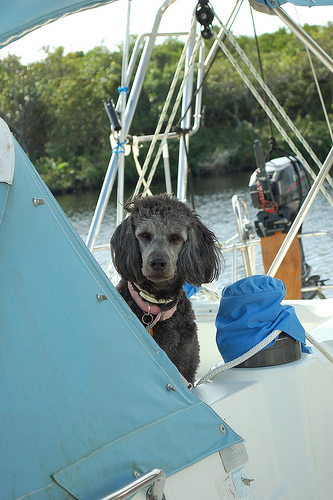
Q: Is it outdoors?
A: Yes, it is outdoors.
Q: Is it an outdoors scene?
A: Yes, it is outdoors.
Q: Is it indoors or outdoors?
A: It is outdoors.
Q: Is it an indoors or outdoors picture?
A: It is outdoors.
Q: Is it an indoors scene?
A: No, it is outdoors.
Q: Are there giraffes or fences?
A: No, there are no fences or giraffes.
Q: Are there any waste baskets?
A: No, there are no waste baskets.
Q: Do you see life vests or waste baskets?
A: No, there are no waste baskets or life vests.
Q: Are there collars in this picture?
A: Yes, there is a collar.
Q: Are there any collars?
A: Yes, there is a collar.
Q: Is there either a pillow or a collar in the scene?
A: Yes, there is a collar.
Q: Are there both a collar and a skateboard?
A: No, there is a collar but no skateboards.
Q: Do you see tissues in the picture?
A: No, there are no tissues.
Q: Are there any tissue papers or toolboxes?
A: No, there are no tissue papers or toolboxes.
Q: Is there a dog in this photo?
A: Yes, there is a dog.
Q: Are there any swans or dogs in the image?
A: Yes, there is a dog.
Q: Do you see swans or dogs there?
A: Yes, there is a dog.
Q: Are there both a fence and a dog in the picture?
A: No, there is a dog but no fences.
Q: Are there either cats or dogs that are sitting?
A: Yes, the dog is sitting.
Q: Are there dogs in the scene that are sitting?
A: Yes, there is a dog that is sitting.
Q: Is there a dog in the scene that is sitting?
A: Yes, there is a dog that is sitting.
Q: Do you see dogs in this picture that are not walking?
A: Yes, there is a dog that is sitting .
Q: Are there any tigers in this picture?
A: No, there are no tigers.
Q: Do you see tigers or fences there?
A: No, there are no tigers or fences.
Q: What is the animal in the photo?
A: The animal is a dog.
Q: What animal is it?
A: The animal is a dog.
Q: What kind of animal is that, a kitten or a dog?
A: This is a dog.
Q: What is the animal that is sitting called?
A: The animal is a dog.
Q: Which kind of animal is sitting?
A: The animal is a dog.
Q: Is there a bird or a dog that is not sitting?
A: No, there is a dog but it is sitting.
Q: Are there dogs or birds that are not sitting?
A: No, there is a dog but it is sitting.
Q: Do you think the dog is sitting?
A: Yes, the dog is sitting.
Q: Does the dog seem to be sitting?
A: Yes, the dog is sitting.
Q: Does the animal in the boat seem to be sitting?
A: Yes, the dog is sitting.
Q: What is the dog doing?
A: The dog is sitting.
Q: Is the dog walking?
A: No, the dog is sitting.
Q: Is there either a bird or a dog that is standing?
A: No, there is a dog but it is sitting.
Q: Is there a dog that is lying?
A: No, there is a dog but it is sitting.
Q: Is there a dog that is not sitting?
A: No, there is a dog but it is sitting.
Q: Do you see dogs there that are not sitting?
A: No, there is a dog but it is sitting.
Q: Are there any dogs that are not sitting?
A: No, there is a dog but it is sitting.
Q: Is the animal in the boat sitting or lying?
A: The dog is sitting.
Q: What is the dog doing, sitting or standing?
A: The dog is sitting.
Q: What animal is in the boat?
A: The dog is in the boat.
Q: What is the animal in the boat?
A: The animal is a dog.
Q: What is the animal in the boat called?
A: The animal is a dog.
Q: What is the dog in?
A: The dog is in the boat.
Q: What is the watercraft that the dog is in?
A: The watercraft is a boat.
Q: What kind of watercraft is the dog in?
A: The dog is in the boat.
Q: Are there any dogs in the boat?
A: Yes, there is a dog in the boat.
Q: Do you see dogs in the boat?
A: Yes, there is a dog in the boat.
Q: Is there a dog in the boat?
A: Yes, there is a dog in the boat.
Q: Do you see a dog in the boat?
A: Yes, there is a dog in the boat.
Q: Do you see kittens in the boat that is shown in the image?
A: No, there is a dog in the boat.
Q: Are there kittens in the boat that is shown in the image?
A: No, there is a dog in the boat.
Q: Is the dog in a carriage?
A: No, the dog is in the boat.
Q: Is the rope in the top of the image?
A: Yes, the rope is in the top of the image.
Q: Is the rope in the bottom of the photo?
A: No, the rope is in the top of the image.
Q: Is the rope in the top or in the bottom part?
A: The rope is in the top of the image.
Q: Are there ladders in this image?
A: No, there are no ladders.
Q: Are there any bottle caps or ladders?
A: No, there are no ladders or bottle caps.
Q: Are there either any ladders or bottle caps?
A: No, there are no ladders or bottle caps.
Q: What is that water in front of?
A: The water is in front of the trees.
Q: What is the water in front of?
A: The water is in front of the trees.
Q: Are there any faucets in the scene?
A: No, there are no faucets.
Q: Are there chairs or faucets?
A: No, there are no faucets or chairs.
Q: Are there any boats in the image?
A: Yes, there is a boat.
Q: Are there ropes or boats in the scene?
A: Yes, there is a boat.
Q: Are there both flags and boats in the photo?
A: No, there is a boat but no flags.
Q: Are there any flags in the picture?
A: No, there are no flags.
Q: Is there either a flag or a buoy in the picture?
A: No, there are no flags or buoys.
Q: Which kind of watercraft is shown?
A: The watercraft is a boat.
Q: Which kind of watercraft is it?
A: The watercraft is a boat.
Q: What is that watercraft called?
A: That is a boat.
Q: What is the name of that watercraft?
A: That is a boat.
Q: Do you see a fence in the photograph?
A: No, there are no fences.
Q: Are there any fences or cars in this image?
A: No, there are no fences or cars.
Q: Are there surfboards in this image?
A: No, there are no surfboards.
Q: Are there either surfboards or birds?
A: No, there are no surfboards or birds.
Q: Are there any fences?
A: No, there are no fences.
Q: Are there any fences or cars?
A: No, there are no fences or cars.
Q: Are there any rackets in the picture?
A: No, there are no rackets.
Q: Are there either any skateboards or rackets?
A: No, there are no rackets or skateboards.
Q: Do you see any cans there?
A: No, there are no cans.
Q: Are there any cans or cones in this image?
A: No, there are no cans or cones.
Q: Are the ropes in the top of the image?
A: Yes, the ropes are in the top of the image.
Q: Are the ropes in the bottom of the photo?
A: No, the ropes are in the top of the image.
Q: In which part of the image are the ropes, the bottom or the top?
A: The ropes are in the top of the image.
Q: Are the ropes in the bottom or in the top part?
A: The ropes are in the top of the image.